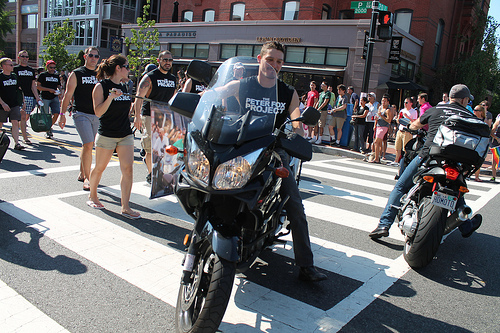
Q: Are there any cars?
A: No, there are no cars.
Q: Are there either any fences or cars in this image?
A: No, there are no cars or fences.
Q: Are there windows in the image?
A: Yes, there is a window.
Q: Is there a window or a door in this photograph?
A: Yes, there is a window.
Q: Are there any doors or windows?
A: Yes, there is a window.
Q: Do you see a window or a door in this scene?
A: Yes, there is a window.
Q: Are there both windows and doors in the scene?
A: No, there is a window but no doors.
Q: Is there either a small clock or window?
A: Yes, there is a small window.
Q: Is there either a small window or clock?
A: Yes, there is a small window.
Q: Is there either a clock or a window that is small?
A: Yes, the window is small.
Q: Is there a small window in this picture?
A: Yes, there is a small window.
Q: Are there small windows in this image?
A: Yes, there is a small window.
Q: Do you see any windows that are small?
A: Yes, there is a window that is small.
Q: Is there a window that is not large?
A: Yes, there is a small window.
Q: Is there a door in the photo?
A: No, there are no doors.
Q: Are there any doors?
A: No, there are no doors.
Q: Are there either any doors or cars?
A: No, there are no doors or cars.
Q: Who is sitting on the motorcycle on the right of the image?
A: The man is sitting on the motorbike.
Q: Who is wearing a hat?
A: The man is wearing a hat.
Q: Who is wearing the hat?
A: The man is wearing a hat.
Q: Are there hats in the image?
A: Yes, there is a hat.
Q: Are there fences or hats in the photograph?
A: Yes, there is a hat.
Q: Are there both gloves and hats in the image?
A: No, there is a hat but no gloves.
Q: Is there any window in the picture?
A: Yes, there is a window.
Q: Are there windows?
A: Yes, there is a window.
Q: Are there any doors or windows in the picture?
A: Yes, there is a window.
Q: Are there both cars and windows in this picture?
A: No, there is a window but no cars.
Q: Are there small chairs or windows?
A: Yes, there is a small window.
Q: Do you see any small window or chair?
A: Yes, there is a small window.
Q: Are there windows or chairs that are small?
A: Yes, the window is small.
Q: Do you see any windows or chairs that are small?
A: Yes, the window is small.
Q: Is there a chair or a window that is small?
A: Yes, the window is small.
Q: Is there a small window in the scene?
A: Yes, there is a small window.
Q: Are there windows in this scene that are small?
A: Yes, there is a window that is small.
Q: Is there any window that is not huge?
A: Yes, there is a small window.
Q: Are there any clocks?
A: No, there are no clocks.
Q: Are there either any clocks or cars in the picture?
A: No, there are no clocks or cars.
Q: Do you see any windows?
A: Yes, there is a window.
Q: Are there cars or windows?
A: Yes, there is a window.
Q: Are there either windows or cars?
A: Yes, there is a window.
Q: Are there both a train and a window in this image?
A: No, there is a window but no trains.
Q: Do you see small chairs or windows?
A: Yes, there is a small window.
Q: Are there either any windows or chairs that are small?
A: Yes, the window is small.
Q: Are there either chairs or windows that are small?
A: Yes, the window is small.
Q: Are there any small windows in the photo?
A: Yes, there is a small window.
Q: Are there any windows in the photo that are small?
A: Yes, there is a window that is small.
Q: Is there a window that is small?
A: Yes, there is a window that is small.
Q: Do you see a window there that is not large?
A: Yes, there is a small window.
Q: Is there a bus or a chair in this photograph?
A: No, there are no buses or chairs.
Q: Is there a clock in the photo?
A: No, there are no clocks.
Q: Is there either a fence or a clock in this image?
A: No, there are no clocks or fences.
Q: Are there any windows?
A: Yes, there is a window.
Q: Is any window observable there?
A: Yes, there is a window.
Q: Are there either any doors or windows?
A: Yes, there is a window.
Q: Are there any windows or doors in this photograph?
A: Yes, there is a window.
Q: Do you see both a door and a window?
A: No, there is a window but no doors.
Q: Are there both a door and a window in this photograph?
A: No, there is a window but no doors.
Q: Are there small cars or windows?
A: Yes, there is a small window.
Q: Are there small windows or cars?
A: Yes, there is a small window.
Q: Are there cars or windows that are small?
A: Yes, the window is small.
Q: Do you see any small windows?
A: Yes, there is a small window.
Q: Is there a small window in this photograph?
A: Yes, there is a small window.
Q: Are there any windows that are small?
A: Yes, there is a window that is small.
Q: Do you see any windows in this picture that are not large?
A: Yes, there is a small window.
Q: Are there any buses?
A: No, there are no buses.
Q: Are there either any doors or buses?
A: No, there are no buses or doors.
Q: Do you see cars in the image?
A: No, there are no cars.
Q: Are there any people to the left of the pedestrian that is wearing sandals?
A: Yes, there is a person to the left of the pedestrian.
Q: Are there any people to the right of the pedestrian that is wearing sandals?
A: No, the person is to the left of the pedestrian.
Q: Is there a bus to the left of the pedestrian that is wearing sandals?
A: No, there is a person to the left of the pedestrian.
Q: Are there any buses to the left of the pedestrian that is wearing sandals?
A: No, there is a person to the left of the pedestrian.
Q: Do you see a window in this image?
A: Yes, there is a window.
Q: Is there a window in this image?
A: Yes, there is a window.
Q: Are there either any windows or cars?
A: Yes, there is a window.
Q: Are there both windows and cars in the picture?
A: No, there is a window but no cars.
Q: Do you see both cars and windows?
A: No, there is a window but no cars.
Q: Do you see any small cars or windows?
A: Yes, there is a small window.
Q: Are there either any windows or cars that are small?
A: Yes, the window is small.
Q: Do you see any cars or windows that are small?
A: Yes, the window is small.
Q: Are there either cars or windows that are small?
A: Yes, the window is small.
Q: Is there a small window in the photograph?
A: Yes, there is a small window.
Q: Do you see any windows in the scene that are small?
A: Yes, there is a window that is small.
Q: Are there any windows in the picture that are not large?
A: Yes, there is a small window.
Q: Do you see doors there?
A: No, there are no doors.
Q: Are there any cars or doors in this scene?
A: No, there are no doors or cars.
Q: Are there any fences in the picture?
A: No, there are no fences.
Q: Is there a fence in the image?
A: No, there are no fences.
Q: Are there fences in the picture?
A: No, there are no fences.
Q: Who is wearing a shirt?
A: The man is wearing a shirt.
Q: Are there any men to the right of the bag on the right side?
A: No, the man is to the left of the bag.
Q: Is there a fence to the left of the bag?
A: No, there is a man to the left of the bag.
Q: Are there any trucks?
A: No, there are no trucks.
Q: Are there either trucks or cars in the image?
A: No, there are no trucks or cars.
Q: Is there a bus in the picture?
A: No, there are no buses.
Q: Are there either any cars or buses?
A: No, there are no buses or cars.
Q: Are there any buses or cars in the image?
A: No, there are no buses or cars.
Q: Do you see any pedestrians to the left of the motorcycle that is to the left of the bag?
A: Yes, there is a pedestrian to the left of the motorbike.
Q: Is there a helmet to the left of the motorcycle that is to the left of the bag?
A: No, there is a pedestrian to the left of the motorcycle.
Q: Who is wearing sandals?
A: The pedestrian is wearing sandals.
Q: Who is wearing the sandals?
A: The pedestrian is wearing sandals.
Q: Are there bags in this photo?
A: Yes, there is a bag.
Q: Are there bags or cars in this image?
A: Yes, there is a bag.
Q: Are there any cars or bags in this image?
A: Yes, there is a bag.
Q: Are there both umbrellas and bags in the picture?
A: No, there is a bag but no umbrellas.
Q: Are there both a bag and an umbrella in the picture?
A: No, there is a bag but no umbrellas.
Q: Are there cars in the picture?
A: No, there are no cars.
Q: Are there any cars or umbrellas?
A: No, there are no cars or umbrellas.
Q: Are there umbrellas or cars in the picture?
A: No, there are no cars or umbrellas.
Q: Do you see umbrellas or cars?
A: No, there are no cars or umbrellas.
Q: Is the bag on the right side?
A: Yes, the bag is on the right of the image.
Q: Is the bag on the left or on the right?
A: The bag is on the right of the image.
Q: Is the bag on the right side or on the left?
A: The bag is on the right of the image.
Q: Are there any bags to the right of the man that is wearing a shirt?
A: Yes, there is a bag to the right of the man.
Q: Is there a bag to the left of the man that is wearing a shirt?
A: No, the bag is to the right of the man.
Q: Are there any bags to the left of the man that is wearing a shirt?
A: No, the bag is to the right of the man.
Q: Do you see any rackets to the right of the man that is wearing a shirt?
A: No, there is a bag to the right of the man.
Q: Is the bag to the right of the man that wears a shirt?
A: Yes, the bag is to the right of the man.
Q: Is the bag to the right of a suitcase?
A: No, the bag is to the right of the man.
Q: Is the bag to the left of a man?
A: No, the bag is to the right of a man.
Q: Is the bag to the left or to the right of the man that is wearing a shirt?
A: The bag is to the right of the man.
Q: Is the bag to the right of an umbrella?
A: No, the bag is to the right of a man.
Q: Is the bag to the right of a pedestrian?
A: Yes, the bag is to the right of a pedestrian.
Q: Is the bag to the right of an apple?
A: No, the bag is to the right of a pedestrian.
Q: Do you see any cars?
A: No, there are no cars.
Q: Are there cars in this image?
A: No, there are no cars.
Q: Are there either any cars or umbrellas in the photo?
A: No, there are no cars or umbrellas.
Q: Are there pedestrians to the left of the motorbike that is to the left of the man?
A: Yes, there is a pedestrian to the left of the motorbike.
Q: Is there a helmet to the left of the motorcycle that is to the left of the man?
A: No, there is a pedestrian to the left of the motorbike.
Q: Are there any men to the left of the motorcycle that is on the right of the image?
A: Yes, there is a man to the left of the motorbike.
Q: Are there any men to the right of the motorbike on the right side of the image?
A: No, the man is to the left of the motorbike.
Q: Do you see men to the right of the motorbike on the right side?
A: No, the man is to the left of the motorbike.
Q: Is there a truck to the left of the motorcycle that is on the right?
A: No, there is a man to the left of the motorbike.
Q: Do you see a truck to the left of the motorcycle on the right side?
A: No, there is a man to the left of the motorbike.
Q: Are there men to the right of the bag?
A: No, the man is to the left of the bag.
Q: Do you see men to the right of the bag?
A: No, the man is to the left of the bag.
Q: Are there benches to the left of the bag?
A: No, there is a man to the left of the bag.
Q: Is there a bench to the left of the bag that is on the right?
A: No, there is a man to the left of the bag.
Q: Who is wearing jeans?
A: The man is wearing jeans.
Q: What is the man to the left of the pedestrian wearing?
A: The man is wearing jeans.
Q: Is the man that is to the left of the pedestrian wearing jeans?
A: Yes, the man is wearing jeans.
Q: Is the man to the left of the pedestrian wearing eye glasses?
A: No, the man is wearing jeans.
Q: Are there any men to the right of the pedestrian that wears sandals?
A: Yes, there is a man to the right of the pedestrian.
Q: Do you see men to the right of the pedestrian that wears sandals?
A: Yes, there is a man to the right of the pedestrian.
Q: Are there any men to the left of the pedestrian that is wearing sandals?
A: No, the man is to the right of the pedestrian.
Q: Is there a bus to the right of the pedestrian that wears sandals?
A: No, there is a man to the right of the pedestrian.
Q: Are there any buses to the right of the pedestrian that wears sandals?
A: No, there is a man to the right of the pedestrian.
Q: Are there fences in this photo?
A: No, there are no fences.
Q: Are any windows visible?
A: Yes, there is a window.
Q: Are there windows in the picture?
A: Yes, there is a window.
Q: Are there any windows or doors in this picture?
A: Yes, there is a window.